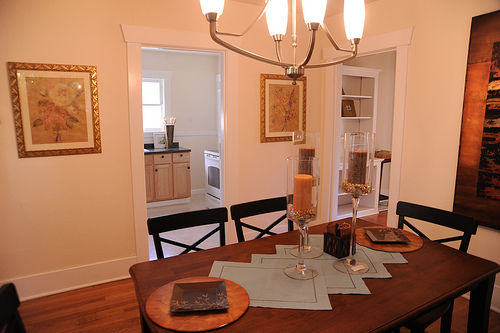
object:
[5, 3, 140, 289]
wall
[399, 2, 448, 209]
wall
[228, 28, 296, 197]
wall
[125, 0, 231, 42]
wall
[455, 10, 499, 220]
painting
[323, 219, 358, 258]
basket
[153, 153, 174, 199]
cabinets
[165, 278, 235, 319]
square plate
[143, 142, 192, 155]
counter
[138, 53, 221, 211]
kitchen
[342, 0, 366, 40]
bulb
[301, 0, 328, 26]
bulb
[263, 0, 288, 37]
bulb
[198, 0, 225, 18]
bulb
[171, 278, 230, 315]
mat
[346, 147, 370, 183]
candle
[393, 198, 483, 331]
dining chair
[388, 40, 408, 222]
frame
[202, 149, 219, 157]
counter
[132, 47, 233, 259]
door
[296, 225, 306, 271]
glass stem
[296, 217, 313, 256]
glass stem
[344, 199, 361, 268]
glass stem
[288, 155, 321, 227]
candle holder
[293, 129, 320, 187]
candle holder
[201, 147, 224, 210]
oven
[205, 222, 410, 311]
placemats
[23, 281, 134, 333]
floor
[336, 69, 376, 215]
bookcase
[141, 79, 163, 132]
window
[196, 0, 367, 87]
chandelier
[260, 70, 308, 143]
artwork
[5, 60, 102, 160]
artwork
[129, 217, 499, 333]
table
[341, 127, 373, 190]
vase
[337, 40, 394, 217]
room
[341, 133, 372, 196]
candle holders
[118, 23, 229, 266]
door frame